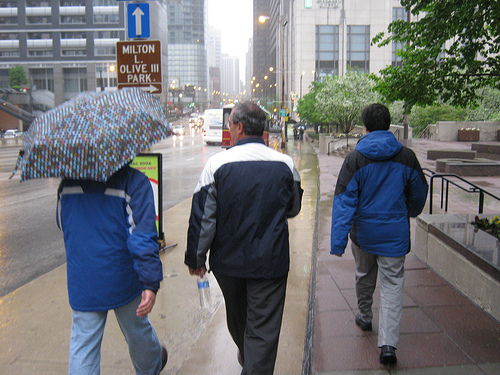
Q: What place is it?
A: It is a sidewalk.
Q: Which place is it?
A: It is a sidewalk.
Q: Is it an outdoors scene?
A: Yes, it is outdoors.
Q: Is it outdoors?
A: Yes, it is outdoors.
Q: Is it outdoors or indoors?
A: It is outdoors.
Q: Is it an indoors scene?
A: No, it is outdoors.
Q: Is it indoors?
A: No, it is outdoors.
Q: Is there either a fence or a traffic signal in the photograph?
A: No, there are no fences or traffic lights.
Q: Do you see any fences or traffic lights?
A: No, there are no fences or traffic lights.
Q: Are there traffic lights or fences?
A: No, there are no fences or traffic lights.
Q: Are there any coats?
A: Yes, there is a coat.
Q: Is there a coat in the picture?
A: Yes, there is a coat.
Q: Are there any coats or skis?
A: Yes, there is a coat.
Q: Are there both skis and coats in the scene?
A: No, there is a coat but no skis.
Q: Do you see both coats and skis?
A: No, there is a coat but no skis.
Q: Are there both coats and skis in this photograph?
A: No, there is a coat but no skis.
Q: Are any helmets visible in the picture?
A: No, there are no helmets.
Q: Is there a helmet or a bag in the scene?
A: No, there are no helmets or bags.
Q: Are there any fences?
A: No, there are no fences.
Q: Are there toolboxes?
A: No, there are no toolboxes.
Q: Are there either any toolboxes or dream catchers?
A: No, there are no toolboxes or dream catchers.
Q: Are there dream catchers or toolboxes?
A: No, there are no toolboxes or dream catchers.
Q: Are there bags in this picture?
A: No, there are no bags.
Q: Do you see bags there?
A: No, there are no bags.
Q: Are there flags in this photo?
A: No, there are no flags.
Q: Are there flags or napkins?
A: No, there are no flags or napkins.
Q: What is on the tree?
A: The flowers are on the tree.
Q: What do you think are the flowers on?
A: The flowers are on the tree.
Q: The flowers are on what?
A: The flowers are on the tree.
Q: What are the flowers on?
A: The flowers are on the tree.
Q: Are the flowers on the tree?
A: Yes, the flowers are on the tree.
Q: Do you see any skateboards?
A: No, there are no skateboards.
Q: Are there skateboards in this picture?
A: No, there are no skateboards.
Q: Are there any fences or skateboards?
A: No, there are no skateboards or fences.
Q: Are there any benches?
A: Yes, there is a bench.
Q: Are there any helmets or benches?
A: Yes, there is a bench.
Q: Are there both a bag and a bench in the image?
A: No, there is a bench but no bags.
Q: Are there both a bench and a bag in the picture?
A: No, there is a bench but no bags.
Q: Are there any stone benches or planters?
A: Yes, there is a stone bench.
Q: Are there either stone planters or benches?
A: Yes, there is a stone bench.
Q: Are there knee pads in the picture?
A: No, there are no knee pads.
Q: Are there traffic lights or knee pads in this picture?
A: No, there are no knee pads or traffic lights.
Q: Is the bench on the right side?
A: Yes, the bench is on the right of the image.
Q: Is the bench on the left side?
A: No, the bench is on the right of the image.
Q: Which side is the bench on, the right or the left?
A: The bench is on the right of the image.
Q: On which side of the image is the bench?
A: The bench is on the right of the image.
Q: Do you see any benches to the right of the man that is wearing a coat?
A: Yes, there is a bench to the right of the man.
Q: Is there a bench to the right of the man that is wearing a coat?
A: Yes, there is a bench to the right of the man.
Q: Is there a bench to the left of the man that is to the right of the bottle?
A: No, the bench is to the right of the man.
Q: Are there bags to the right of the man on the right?
A: No, there is a bench to the right of the man.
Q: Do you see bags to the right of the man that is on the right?
A: No, there is a bench to the right of the man.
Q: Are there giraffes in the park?
A: No, there is a bench in the park.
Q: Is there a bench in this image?
A: Yes, there is a bench.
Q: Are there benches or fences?
A: Yes, there is a bench.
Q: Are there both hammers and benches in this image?
A: No, there is a bench but no hammers.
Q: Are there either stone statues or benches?
A: Yes, there is a stone bench.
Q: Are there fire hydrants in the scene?
A: No, there are no fire hydrants.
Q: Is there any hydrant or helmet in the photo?
A: No, there are no fire hydrants or helmets.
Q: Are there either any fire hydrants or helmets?
A: No, there are no fire hydrants or helmets.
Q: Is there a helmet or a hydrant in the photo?
A: No, there are no fire hydrants or helmets.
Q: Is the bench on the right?
A: Yes, the bench is on the right of the image.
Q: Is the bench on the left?
A: No, the bench is on the right of the image.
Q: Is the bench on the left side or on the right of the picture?
A: The bench is on the right of the image.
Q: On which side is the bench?
A: The bench is on the right of the image.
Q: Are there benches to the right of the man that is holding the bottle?
A: Yes, there is a bench to the right of the man.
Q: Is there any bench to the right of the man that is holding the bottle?
A: Yes, there is a bench to the right of the man.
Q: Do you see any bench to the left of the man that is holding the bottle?
A: No, the bench is to the right of the man.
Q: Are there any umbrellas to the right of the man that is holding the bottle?
A: No, there is a bench to the right of the man.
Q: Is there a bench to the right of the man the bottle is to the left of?
A: Yes, there is a bench to the right of the man.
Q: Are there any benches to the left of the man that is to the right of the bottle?
A: No, the bench is to the right of the man.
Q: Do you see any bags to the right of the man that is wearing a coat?
A: No, there is a bench to the right of the man.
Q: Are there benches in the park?
A: Yes, there is a bench in the park.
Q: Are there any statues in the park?
A: No, there is a bench in the park.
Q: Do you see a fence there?
A: No, there are no fences.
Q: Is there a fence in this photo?
A: No, there are no fences.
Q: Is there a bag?
A: No, there are no bags.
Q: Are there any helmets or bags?
A: No, there are no bags or helmets.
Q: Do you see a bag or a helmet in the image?
A: No, there are no bags or helmets.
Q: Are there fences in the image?
A: No, there are no fences.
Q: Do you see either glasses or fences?
A: No, there are no fences or glasses.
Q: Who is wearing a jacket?
A: The man is wearing a jacket.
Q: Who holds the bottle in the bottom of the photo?
A: The man holds the bottle.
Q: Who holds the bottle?
A: The man holds the bottle.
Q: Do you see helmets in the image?
A: No, there are no helmets.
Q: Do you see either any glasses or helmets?
A: No, there are no helmets or glasses.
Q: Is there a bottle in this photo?
A: Yes, there is a bottle.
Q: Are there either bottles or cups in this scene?
A: Yes, there is a bottle.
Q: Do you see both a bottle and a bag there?
A: No, there is a bottle but no bags.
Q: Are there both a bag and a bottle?
A: No, there is a bottle but no bags.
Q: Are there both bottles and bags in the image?
A: No, there is a bottle but no bags.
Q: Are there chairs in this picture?
A: No, there are no chairs.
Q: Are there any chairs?
A: No, there are no chairs.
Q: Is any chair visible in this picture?
A: No, there are no chairs.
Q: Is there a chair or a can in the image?
A: No, there are no chairs or cans.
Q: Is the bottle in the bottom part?
A: Yes, the bottle is in the bottom of the image.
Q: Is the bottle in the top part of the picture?
A: No, the bottle is in the bottom of the image.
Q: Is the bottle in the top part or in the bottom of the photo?
A: The bottle is in the bottom of the image.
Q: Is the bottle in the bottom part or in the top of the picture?
A: The bottle is in the bottom of the image.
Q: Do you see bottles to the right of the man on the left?
A: Yes, there is a bottle to the right of the man.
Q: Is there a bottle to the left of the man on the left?
A: No, the bottle is to the right of the man.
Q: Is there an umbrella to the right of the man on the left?
A: No, there is a bottle to the right of the man.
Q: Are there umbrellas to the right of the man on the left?
A: No, there is a bottle to the right of the man.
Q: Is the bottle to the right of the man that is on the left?
A: Yes, the bottle is to the right of the man.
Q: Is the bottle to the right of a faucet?
A: No, the bottle is to the right of the man.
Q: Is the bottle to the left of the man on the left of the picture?
A: No, the bottle is to the right of the man.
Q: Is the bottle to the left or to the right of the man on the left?
A: The bottle is to the right of the man.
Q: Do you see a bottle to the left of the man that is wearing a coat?
A: Yes, there is a bottle to the left of the man.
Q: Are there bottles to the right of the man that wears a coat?
A: No, the bottle is to the left of the man.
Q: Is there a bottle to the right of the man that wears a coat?
A: No, the bottle is to the left of the man.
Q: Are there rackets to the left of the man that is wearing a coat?
A: No, there is a bottle to the left of the man.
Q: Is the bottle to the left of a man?
A: Yes, the bottle is to the left of a man.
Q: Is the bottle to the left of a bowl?
A: No, the bottle is to the left of a man.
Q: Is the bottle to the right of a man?
A: No, the bottle is to the left of a man.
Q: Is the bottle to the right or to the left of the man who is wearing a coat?
A: The bottle is to the left of the man.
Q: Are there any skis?
A: No, there are no skis.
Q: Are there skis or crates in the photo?
A: No, there are no skis or crates.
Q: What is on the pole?
A: The sign is on the pole.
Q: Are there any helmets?
A: No, there are no helmets.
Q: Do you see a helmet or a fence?
A: No, there are no helmets or fences.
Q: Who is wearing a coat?
A: The man is wearing a coat.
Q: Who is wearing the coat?
A: The man is wearing a coat.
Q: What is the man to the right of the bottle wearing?
A: The man is wearing a coat.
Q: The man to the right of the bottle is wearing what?
A: The man is wearing a coat.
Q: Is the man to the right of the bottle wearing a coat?
A: Yes, the man is wearing a coat.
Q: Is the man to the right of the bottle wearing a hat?
A: No, the man is wearing a coat.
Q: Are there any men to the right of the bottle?
A: Yes, there is a man to the right of the bottle.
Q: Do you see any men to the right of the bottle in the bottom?
A: Yes, there is a man to the right of the bottle.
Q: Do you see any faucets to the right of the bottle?
A: No, there is a man to the right of the bottle.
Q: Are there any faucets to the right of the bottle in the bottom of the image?
A: No, there is a man to the right of the bottle.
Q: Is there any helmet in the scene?
A: No, there are no helmets.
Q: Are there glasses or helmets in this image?
A: No, there are no helmets or glasses.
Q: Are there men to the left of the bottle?
A: Yes, there is a man to the left of the bottle.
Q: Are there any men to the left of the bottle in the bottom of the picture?
A: Yes, there is a man to the left of the bottle.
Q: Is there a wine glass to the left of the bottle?
A: No, there is a man to the left of the bottle.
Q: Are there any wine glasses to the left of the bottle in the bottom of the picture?
A: No, there is a man to the left of the bottle.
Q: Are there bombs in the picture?
A: No, there are no bombs.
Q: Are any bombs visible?
A: No, there are no bombs.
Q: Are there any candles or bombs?
A: No, there are no bombs or candles.